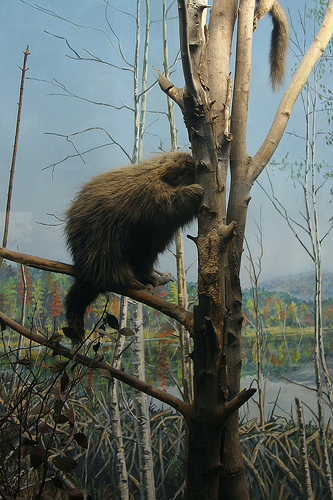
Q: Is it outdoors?
A: Yes, it is outdoors.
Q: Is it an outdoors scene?
A: Yes, it is outdoors.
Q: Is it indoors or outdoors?
A: It is outdoors.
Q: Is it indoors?
A: No, it is outdoors.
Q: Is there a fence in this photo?
A: No, there are no fences.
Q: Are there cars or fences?
A: No, there are no fences or cars.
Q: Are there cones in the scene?
A: No, there are no cones.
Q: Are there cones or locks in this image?
A: No, there are no cones or locks.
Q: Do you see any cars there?
A: No, there are no cars.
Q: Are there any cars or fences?
A: No, there are no cars or fences.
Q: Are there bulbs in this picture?
A: No, there are no bulbs.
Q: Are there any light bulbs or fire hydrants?
A: No, there are no light bulbs or fire hydrants.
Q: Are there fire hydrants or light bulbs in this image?
A: No, there are no light bulbs or fire hydrants.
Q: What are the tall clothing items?
A: The clothing items are trunks.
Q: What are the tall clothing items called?
A: The clothing items are trunks.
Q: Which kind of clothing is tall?
A: The clothing is trunks.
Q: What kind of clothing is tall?
A: The clothing is trunks.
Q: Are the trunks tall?
A: Yes, the trunks are tall.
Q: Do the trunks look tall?
A: Yes, the trunks are tall.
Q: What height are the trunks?
A: The trunks are tall.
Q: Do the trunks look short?
A: No, the trunks are tall.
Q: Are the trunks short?
A: No, the trunks are tall.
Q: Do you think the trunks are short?
A: No, the trunks are tall.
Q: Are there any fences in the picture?
A: No, there are no fences.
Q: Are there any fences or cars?
A: No, there are no fences or cars.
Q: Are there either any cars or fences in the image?
A: No, there are no fences or cars.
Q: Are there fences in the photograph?
A: No, there are no fences.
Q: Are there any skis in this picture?
A: No, there are no skis.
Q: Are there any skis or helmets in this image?
A: No, there are no skis or helmets.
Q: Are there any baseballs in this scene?
A: No, there are no baseballs.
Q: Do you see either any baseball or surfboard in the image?
A: No, there are no baseballs or surfboards.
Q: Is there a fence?
A: No, there are no fences.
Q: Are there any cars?
A: No, there are no cars.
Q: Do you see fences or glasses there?
A: No, there are no fences or glasses.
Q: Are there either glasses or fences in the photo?
A: No, there are no fences or glasses.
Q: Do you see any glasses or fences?
A: No, there are no fences or glasses.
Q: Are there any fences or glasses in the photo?
A: No, there are no fences or glasses.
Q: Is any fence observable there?
A: No, there are no fences.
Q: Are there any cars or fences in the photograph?
A: No, there are no fences or cars.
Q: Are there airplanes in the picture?
A: No, there are no airplanes.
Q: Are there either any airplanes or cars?
A: No, there are no airplanes or cars.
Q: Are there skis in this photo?
A: No, there are no skis.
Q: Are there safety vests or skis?
A: No, there are no skis or safety vests.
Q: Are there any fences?
A: No, there are no fences.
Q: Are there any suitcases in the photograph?
A: No, there are no suitcases.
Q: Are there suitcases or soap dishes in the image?
A: No, there are no suitcases or soap dishes.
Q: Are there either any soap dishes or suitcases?
A: No, there are no suitcases or soap dishes.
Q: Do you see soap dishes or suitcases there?
A: No, there are no suitcases or soap dishes.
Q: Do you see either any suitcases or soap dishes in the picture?
A: No, there are no suitcases or soap dishes.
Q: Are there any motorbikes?
A: No, there are no motorbikes.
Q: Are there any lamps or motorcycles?
A: No, there are no motorcycles or lamps.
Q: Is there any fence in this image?
A: No, there are no fences.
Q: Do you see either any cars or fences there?
A: No, there are no fences or cars.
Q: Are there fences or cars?
A: No, there are no fences or cars.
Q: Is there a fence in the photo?
A: No, there are no fences.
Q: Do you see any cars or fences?
A: No, there are no fences or cars.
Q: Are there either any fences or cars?
A: No, there are no fences or cars.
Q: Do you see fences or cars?
A: No, there are no fences or cars.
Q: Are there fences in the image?
A: No, there are no fences.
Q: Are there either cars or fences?
A: No, there are no fences or cars.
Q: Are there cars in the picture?
A: No, there are no cars.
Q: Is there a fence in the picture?
A: No, there are no fences.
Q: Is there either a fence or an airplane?
A: No, there are no fences or airplanes.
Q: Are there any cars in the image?
A: No, there are no cars.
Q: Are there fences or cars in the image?
A: No, there are no cars or fences.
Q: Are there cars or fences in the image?
A: No, there are no cars or fences.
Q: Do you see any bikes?
A: No, there are no bikes.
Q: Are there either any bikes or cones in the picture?
A: No, there are no bikes or cones.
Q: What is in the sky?
A: The clouds are in the sky.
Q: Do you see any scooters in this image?
A: No, there are no scooters.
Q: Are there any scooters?
A: No, there are no scooters.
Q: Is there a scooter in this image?
A: No, there are no scooters.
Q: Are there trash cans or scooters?
A: No, there are no scooters or trash cans.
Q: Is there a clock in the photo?
A: No, there are no clocks.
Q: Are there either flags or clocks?
A: No, there are no clocks or flags.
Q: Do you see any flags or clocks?
A: No, there are no clocks or flags.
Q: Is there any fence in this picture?
A: No, there are no fences.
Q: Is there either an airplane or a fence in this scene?
A: No, there are no fences or airplanes.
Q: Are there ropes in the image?
A: No, there are no ropes.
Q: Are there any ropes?
A: No, there are no ropes.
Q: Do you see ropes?
A: No, there are no ropes.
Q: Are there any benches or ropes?
A: No, there are no ropes or benches.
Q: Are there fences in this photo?
A: No, there are no fences.